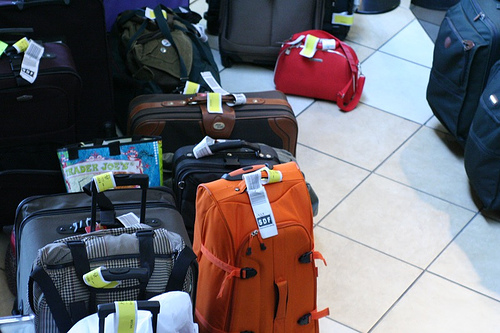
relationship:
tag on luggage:
[242, 171, 278, 240] [192, 162, 329, 332]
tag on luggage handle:
[92, 171, 117, 193] [91, 172, 148, 231]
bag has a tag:
[274, 28, 366, 111] [300, 34, 319, 58]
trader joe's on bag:
[65, 162, 127, 177] [55, 133, 163, 192]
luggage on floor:
[464, 60, 499, 213] [0, 0, 499, 333]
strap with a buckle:
[200, 244, 246, 299] [239, 265, 257, 280]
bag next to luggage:
[55, 133, 163, 192] [15, 172, 192, 316]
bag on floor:
[274, 28, 366, 111] [0, 0, 499, 333]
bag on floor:
[55, 133, 163, 192] [0, 0, 499, 333]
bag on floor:
[27, 224, 199, 332] [0, 0, 499, 333]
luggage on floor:
[192, 162, 329, 332] [0, 0, 499, 333]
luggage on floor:
[15, 172, 192, 316] [0, 0, 499, 333]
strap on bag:
[291, 29, 365, 112] [274, 28, 366, 111]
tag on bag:
[300, 34, 319, 58] [274, 28, 366, 111]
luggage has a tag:
[192, 162, 329, 332] [242, 171, 278, 240]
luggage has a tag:
[127, 92, 297, 157] [207, 92, 224, 114]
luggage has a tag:
[67, 290, 199, 332] [115, 299, 138, 332]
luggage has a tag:
[0, 37, 83, 234] [19, 38, 44, 83]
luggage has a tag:
[15, 172, 192, 316] [92, 171, 117, 193]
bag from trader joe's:
[55, 133, 163, 192] [65, 162, 127, 177]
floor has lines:
[0, 0, 499, 333] [0, 0, 499, 333]